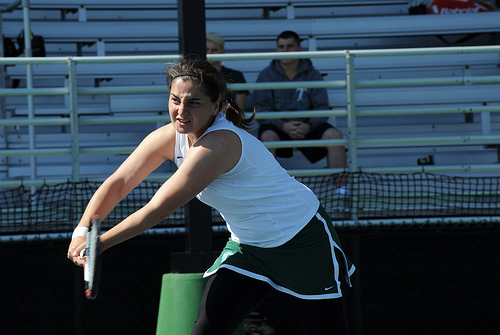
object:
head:
[163, 58, 224, 135]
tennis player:
[67, 57, 360, 334]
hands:
[72, 238, 100, 266]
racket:
[76, 217, 101, 301]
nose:
[178, 104, 189, 116]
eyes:
[189, 101, 201, 106]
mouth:
[175, 117, 192, 127]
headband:
[171, 73, 202, 80]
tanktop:
[172, 112, 320, 249]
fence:
[0, 46, 499, 243]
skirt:
[202, 205, 357, 301]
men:
[247, 31, 347, 184]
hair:
[159, 55, 257, 129]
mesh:
[0, 171, 500, 243]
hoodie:
[252, 54, 330, 127]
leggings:
[200, 276, 265, 334]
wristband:
[71, 226, 89, 238]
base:
[154, 272, 207, 335]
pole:
[173, 1, 215, 271]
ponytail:
[224, 99, 259, 129]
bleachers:
[0, 10, 500, 43]